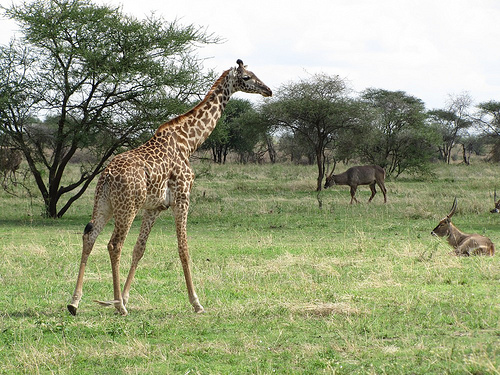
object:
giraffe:
[66, 59, 273, 316]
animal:
[66, 59, 271, 316]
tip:
[67, 302, 78, 316]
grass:
[308, 262, 438, 337]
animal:
[430, 200, 495, 257]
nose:
[430, 232, 435, 238]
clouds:
[312, 2, 495, 68]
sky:
[250, 0, 390, 67]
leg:
[174, 208, 201, 306]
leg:
[106, 213, 131, 310]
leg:
[121, 210, 159, 299]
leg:
[68, 209, 109, 303]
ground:
[0, 164, 499, 367]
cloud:
[204, 0, 497, 75]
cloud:
[269, 61, 495, 90]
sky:
[0, 3, 495, 136]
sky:
[232, 6, 464, 70]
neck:
[200, 76, 234, 122]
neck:
[156, 71, 235, 145]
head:
[225, 60, 273, 98]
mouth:
[260, 81, 273, 101]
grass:
[279, 247, 367, 299]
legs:
[105, 207, 136, 301]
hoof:
[66, 304, 78, 315]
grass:
[37, 220, 494, 374]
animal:
[430, 195, 495, 258]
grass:
[262, 223, 463, 350]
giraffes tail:
[83, 171, 106, 236]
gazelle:
[430, 200, 494, 257]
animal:
[323, 165, 387, 205]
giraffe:
[87, 63, 256, 297]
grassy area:
[243, 241, 427, 341]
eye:
[242, 73, 252, 82]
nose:
[265, 89, 275, 96]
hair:
[164, 86, 211, 123]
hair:
[84, 220, 92, 235]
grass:
[10, 320, 496, 370]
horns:
[446, 193, 459, 218]